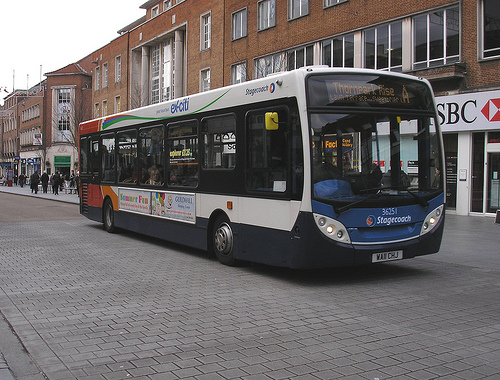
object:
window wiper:
[335, 185, 389, 217]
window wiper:
[397, 188, 432, 210]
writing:
[363, 208, 413, 229]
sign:
[322, 76, 430, 107]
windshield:
[310, 109, 445, 209]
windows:
[201, 114, 239, 170]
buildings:
[0, 0, 500, 218]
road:
[0, 185, 499, 378]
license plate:
[369, 249, 403, 264]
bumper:
[299, 206, 445, 271]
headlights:
[333, 230, 345, 241]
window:
[309, 110, 444, 210]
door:
[464, 130, 498, 215]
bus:
[78, 62, 447, 272]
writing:
[167, 97, 191, 117]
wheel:
[213, 212, 242, 263]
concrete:
[69, 279, 226, 314]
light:
[420, 223, 432, 232]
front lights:
[318, 216, 327, 227]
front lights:
[434, 205, 442, 217]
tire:
[100, 199, 115, 233]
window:
[138, 121, 164, 187]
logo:
[364, 215, 411, 227]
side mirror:
[264, 112, 276, 130]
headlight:
[322, 222, 337, 237]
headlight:
[425, 214, 437, 227]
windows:
[480, 0, 500, 50]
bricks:
[170, 366, 200, 379]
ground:
[1, 185, 500, 378]